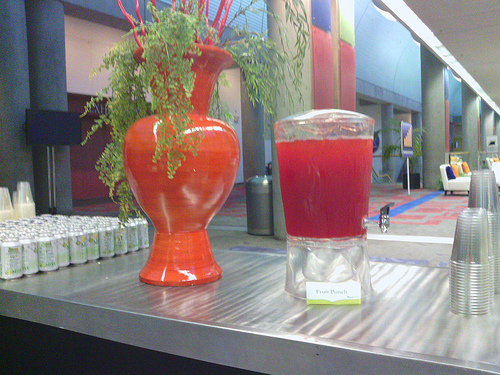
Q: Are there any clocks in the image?
A: No, there are no clocks.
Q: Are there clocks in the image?
A: No, there are no clocks.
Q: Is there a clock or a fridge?
A: No, there are no clocks or refrigerators.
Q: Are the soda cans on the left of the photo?
A: Yes, the soda cans are on the left of the image.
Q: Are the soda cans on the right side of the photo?
A: No, the soda cans are on the left of the image.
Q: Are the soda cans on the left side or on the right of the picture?
A: The soda cans are on the left of the image.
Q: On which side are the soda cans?
A: The soda cans are on the left of the image.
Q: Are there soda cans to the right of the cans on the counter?
A: Yes, there are soda cans to the right of the cans.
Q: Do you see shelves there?
A: No, there are no shelves.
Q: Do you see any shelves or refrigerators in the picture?
A: No, there are no shelves or refrigerators.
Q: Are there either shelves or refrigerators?
A: No, there are no shelves or refrigerators.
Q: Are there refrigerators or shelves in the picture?
A: No, there are no shelves or refrigerators.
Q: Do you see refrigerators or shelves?
A: No, there are no shelves or refrigerators.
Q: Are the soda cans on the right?
A: No, the soda cans are on the left of the image.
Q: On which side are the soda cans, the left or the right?
A: The soda cans are on the left of the image.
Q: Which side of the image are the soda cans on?
A: The soda cans are on the left of the image.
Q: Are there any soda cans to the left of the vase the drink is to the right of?
A: Yes, there are soda cans to the left of the vase.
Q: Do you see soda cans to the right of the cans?
A: Yes, there are soda cans to the right of the cans.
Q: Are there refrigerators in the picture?
A: No, there are no refrigerators.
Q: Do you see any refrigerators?
A: No, there are no refrigerators.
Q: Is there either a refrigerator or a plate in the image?
A: No, there are no refrigerators or plates.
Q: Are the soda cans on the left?
A: Yes, the soda cans are on the left of the image.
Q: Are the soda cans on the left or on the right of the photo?
A: The soda cans are on the left of the image.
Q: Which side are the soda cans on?
A: The soda cans are on the left of the image.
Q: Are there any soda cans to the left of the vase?
A: Yes, there are soda cans to the left of the vase.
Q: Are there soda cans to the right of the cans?
A: Yes, there are soda cans to the right of the cans.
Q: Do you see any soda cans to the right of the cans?
A: Yes, there are soda cans to the right of the cans.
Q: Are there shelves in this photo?
A: No, there are no shelves.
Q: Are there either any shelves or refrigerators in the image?
A: No, there are no shelves or refrigerators.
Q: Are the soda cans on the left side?
A: Yes, the soda cans are on the left of the image.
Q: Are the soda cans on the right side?
A: No, the soda cans are on the left of the image.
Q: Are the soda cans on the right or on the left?
A: The soda cans are on the left of the image.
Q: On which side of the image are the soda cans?
A: The soda cans are on the left of the image.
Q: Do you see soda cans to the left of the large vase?
A: Yes, there are soda cans to the left of the vase.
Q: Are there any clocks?
A: No, there are no clocks.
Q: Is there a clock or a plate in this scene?
A: No, there are no clocks or plates.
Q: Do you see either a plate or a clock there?
A: No, there are no clocks or plates.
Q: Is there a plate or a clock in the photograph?
A: No, there are no clocks or plates.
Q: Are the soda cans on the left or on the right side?
A: The soda cans are on the left of the image.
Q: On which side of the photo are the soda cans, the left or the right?
A: The soda cans are on the left of the image.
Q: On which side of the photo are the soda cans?
A: The soda cans are on the left of the image.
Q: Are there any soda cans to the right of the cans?
A: Yes, there are soda cans to the right of the cans.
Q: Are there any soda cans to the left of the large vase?
A: Yes, there are soda cans to the left of the vase.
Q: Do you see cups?
A: Yes, there is a cup.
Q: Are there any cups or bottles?
A: Yes, there is a cup.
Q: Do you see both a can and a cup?
A: Yes, there are both a cup and a can.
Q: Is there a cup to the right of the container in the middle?
A: Yes, there is a cup to the right of the container.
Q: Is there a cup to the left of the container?
A: No, the cup is to the right of the container.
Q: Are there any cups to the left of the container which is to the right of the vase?
A: No, the cup is to the right of the container.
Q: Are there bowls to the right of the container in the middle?
A: No, there is a cup to the right of the container.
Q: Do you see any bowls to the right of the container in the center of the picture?
A: No, there is a cup to the right of the container.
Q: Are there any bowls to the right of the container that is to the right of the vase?
A: No, there is a cup to the right of the container.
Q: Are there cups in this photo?
A: Yes, there is a cup.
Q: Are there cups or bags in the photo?
A: Yes, there is a cup.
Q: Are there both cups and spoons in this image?
A: No, there is a cup but no spoons.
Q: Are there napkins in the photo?
A: No, there are no napkins.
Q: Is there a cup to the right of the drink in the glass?
A: Yes, there is a cup to the right of the drink.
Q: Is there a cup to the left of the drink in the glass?
A: No, the cup is to the right of the drink.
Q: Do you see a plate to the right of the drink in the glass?
A: No, there is a cup to the right of the drink.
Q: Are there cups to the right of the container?
A: Yes, there is a cup to the right of the container.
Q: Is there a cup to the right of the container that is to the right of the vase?
A: Yes, there is a cup to the right of the container.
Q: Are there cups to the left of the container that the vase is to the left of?
A: No, the cup is to the right of the container.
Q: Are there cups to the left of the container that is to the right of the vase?
A: No, the cup is to the right of the container.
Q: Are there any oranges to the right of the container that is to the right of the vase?
A: No, there is a cup to the right of the container.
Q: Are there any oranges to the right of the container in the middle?
A: No, there is a cup to the right of the container.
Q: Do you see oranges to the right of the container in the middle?
A: No, there is a cup to the right of the container.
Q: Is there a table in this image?
A: Yes, there is a table.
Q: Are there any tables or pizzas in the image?
A: Yes, there is a table.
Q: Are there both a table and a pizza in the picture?
A: No, there is a table but no pizzas.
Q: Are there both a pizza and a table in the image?
A: No, there is a table but no pizzas.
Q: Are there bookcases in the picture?
A: No, there are no bookcases.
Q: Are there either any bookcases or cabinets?
A: No, there are no bookcases or cabinets.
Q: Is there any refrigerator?
A: No, there are no refrigerators.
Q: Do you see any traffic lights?
A: No, there are no traffic lights.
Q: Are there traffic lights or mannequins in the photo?
A: No, there are no traffic lights or mannequins.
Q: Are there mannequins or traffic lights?
A: No, there are no traffic lights or mannequins.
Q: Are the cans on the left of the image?
A: Yes, the cans are on the left of the image.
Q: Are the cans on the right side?
A: No, the cans are on the left of the image.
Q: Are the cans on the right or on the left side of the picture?
A: The cans are on the left of the image.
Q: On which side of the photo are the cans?
A: The cans are on the left of the image.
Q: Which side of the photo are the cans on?
A: The cans are on the left of the image.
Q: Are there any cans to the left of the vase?
A: Yes, there are cans to the left of the vase.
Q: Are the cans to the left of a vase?
A: Yes, the cans are to the left of a vase.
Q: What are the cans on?
A: The cans are on the counter.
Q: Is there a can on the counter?
A: Yes, there are cans on the counter.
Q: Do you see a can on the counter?
A: Yes, there are cans on the counter.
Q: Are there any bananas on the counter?
A: No, there are cans on the counter.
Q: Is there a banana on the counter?
A: No, there are cans on the counter.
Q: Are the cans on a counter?
A: Yes, the cans are on a counter.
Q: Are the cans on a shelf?
A: No, the cans are on a counter.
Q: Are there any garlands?
A: No, there are no garlands.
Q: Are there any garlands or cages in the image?
A: No, there are no garlands or cages.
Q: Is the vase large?
A: Yes, the vase is large.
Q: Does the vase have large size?
A: Yes, the vase is large.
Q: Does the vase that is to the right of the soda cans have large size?
A: Yes, the vase is large.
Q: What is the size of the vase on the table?
A: The vase is large.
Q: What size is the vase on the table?
A: The vase is large.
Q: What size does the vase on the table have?
A: The vase has large size.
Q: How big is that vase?
A: The vase is large.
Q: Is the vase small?
A: No, the vase is large.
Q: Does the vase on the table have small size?
A: No, the vase is large.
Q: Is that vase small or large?
A: The vase is large.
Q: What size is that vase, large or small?
A: The vase is large.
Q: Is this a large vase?
A: Yes, this is a large vase.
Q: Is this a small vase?
A: No, this is a large vase.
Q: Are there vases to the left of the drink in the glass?
A: Yes, there is a vase to the left of the drink.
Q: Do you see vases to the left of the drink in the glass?
A: Yes, there is a vase to the left of the drink.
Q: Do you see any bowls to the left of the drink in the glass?
A: No, there is a vase to the left of the drink.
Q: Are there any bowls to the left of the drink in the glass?
A: No, there is a vase to the left of the drink.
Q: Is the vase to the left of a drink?
A: Yes, the vase is to the left of a drink.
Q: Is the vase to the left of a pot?
A: No, the vase is to the left of a drink.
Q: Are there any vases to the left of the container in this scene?
A: Yes, there is a vase to the left of the container.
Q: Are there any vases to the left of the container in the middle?
A: Yes, there is a vase to the left of the container.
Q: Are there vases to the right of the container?
A: No, the vase is to the left of the container.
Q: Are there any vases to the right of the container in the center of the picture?
A: No, the vase is to the left of the container.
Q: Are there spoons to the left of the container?
A: No, there is a vase to the left of the container.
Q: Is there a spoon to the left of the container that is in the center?
A: No, there is a vase to the left of the container.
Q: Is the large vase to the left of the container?
A: Yes, the vase is to the left of the container.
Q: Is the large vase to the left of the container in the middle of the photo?
A: Yes, the vase is to the left of the container.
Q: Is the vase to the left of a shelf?
A: No, the vase is to the left of the container.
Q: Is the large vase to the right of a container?
A: No, the vase is to the left of a container.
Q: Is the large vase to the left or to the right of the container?
A: The vase is to the left of the container.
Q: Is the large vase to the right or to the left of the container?
A: The vase is to the left of the container.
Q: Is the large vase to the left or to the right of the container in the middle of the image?
A: The vase is to the left of the container.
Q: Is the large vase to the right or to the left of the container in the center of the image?
A: The vase is to the left of the container.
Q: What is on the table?
A: The vase is on the table.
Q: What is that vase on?
A: The vase is on the table.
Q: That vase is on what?
A: The vase is on the table.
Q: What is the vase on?
A: The vase is on the table.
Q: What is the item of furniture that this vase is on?
A: The piece of furniture is a table.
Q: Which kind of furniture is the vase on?
A: The vase is on the table.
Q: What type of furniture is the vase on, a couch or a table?
A: The vase is on a table.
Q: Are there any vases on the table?
A: Yes, there is a vase on the table.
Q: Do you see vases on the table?
A: Yes, there is a vase on the table.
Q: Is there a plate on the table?
A: No, there is a vase on the table.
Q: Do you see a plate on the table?
A: No, there is a vase on the table.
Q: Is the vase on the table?
A: Yes, the vase is on the table.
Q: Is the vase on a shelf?
A: No, the vase is on the table.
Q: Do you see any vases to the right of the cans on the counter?
A: Yes, there is a vase to the right of the cans.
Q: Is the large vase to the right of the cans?
A: Yes, the vase is to the right of the cans.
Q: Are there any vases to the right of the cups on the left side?
A: Yes, there is a vase to the right of the cups.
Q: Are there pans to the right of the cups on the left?
A: No, there is a vase to the right of the cups.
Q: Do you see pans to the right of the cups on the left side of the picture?
A: No, there is a vase to the right of the cups.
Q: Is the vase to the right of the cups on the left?
A: Yes, the vase is to the right of the cups.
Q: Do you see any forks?
A: No, there are no forks.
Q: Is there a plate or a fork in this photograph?
A: No, there are no forks or plates.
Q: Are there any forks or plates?
A: No, there are no forks or plates.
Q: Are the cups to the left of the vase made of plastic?
A: Yes, the cups are made of plastic.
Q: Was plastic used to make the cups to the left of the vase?
A: Yes, the cups are made of plastic.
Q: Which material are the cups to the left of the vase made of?
A: The cups are made of plastic.